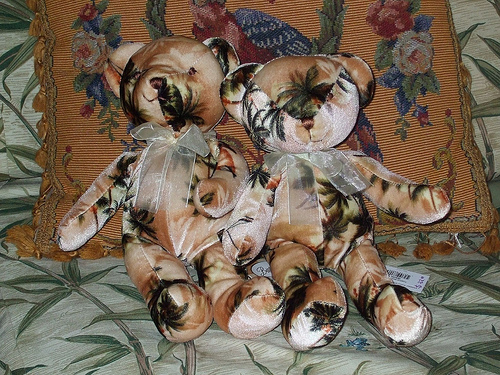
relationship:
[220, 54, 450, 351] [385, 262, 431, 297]
bear has a tag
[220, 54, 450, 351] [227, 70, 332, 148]
bear has print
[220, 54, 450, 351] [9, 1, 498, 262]
bear on a pillow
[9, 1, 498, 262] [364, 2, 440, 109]
pillow has flowers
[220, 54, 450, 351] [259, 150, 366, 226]
bear has bow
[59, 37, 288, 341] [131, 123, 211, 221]
bear has bow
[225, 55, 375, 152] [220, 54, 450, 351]
face of a bear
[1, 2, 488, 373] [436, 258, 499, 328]
blanket has green leaves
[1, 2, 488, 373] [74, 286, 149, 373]
blanket has brown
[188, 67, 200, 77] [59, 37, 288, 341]
eye of a bear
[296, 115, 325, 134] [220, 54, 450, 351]
nose of a bear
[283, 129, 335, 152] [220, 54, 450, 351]
mouth of a bear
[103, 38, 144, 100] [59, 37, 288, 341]
ear of a bear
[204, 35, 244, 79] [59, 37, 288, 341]
ear of a bear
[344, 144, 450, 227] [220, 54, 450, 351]
arm of a bear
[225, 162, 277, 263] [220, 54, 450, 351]
arm of a bear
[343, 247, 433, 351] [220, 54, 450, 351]
leg of a bear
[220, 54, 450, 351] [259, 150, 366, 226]
bear has a bow